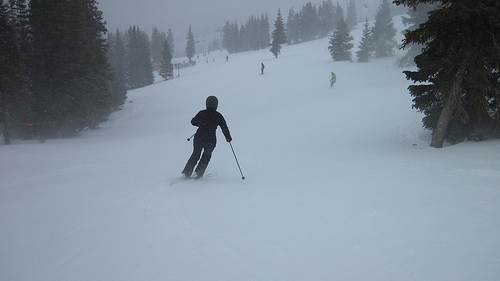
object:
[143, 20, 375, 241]
ski slope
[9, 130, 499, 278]
ground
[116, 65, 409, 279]
snow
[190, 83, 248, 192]
skier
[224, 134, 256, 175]
ski pole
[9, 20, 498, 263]
winter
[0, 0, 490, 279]
area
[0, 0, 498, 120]
trees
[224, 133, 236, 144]
hand